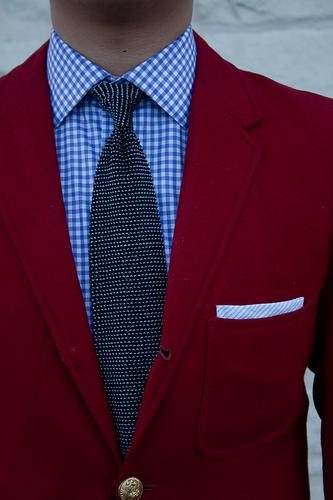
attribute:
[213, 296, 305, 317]
stripes — white, blue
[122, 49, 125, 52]
freckle — small, brown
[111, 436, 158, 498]
button — silver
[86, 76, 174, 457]
tie — hanging down